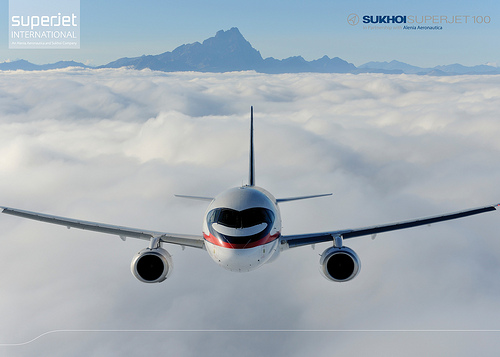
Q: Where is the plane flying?
A: In the white clouds.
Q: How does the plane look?
A: It is large.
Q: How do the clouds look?
A: They are fluffy.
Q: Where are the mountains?
A: They are far away.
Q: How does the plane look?
A: It is white.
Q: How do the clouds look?
A: They are white.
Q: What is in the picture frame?
A: The two jets.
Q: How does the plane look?
A: The plane is white.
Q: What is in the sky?
A: A plane.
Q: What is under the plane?
A: Clouds.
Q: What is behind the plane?
A: Mountains.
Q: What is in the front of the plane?
A: The nose.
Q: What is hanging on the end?
A: The tail.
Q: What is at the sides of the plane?
A: The wings.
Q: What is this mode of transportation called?
A: Airplane.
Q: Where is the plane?
A: In the air.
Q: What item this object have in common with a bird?
A: Wing.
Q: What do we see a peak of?
A: Mountain.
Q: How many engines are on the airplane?
A: 2.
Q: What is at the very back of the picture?
A: Mountains.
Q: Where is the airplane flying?
A: Above the clouds.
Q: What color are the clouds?
A: White.